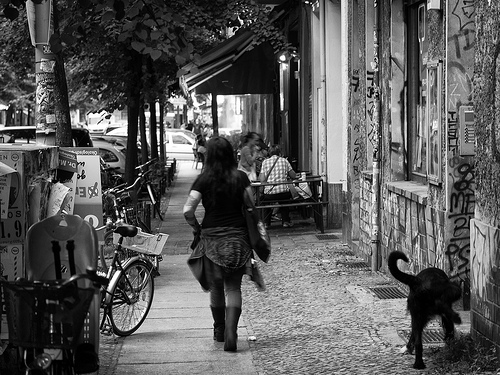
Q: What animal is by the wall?
A: A dog.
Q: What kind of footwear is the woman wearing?
A: Boots.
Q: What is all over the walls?
A: Graffiti.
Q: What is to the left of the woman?
A: A bicycle.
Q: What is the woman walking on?
A: A sidewalk.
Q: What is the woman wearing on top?
A: A black shirt.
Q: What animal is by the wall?
A: A dog.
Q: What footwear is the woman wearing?
A: Boots.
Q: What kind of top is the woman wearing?
A: A black shirt.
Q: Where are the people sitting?
A: At picnic tables.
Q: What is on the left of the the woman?
A: A bike.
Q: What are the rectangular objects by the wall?
A: Grates.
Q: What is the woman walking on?
A: The sidewalk.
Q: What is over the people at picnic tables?
A: An awning.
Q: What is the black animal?
A: A dog.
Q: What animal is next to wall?
A: Dog.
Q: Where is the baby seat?
A: On a bike.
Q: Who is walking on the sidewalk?
A: Woman in boots.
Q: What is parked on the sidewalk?
A: Bike.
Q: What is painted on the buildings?
A: Graffiti.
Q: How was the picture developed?
A: Black and white.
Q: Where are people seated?
A: Tables outside cafe.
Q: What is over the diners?
A: Awning.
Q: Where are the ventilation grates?
A: Sidewalk along buildings.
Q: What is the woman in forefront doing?
A: Walking down sidewalk.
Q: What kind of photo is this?
A: Black and white.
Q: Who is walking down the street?
A: A woman.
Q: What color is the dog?
A: Black.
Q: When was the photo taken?
A: Daytime.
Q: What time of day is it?
A: Afternoon.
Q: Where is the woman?
A: On the sidewalk.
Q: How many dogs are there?
A: One.